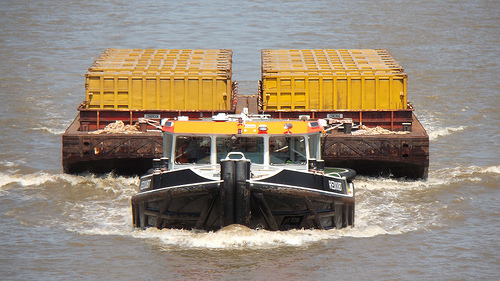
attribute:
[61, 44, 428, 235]
tugboat — large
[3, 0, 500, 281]
water — spray, moving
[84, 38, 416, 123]
stuff — large, yellow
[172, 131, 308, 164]
windows — glass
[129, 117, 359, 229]
boat — large, black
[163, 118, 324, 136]
top — safety, yellow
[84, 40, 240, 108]
container — yellow, rectangular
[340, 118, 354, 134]
barrel — black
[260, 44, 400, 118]
containers — yellow